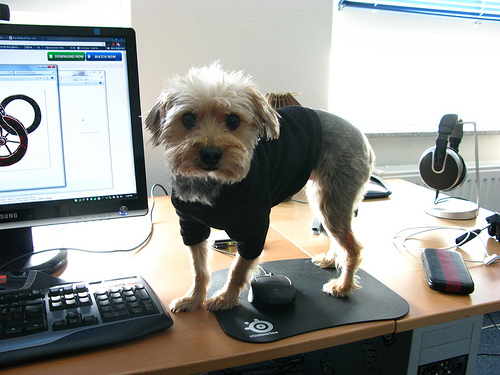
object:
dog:
[145, 64, 376, 314]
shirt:
[172, 105, 321, 259]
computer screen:
[0, 35, 137, 204]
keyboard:
[0, 272, 174, 364]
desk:
[0, 177, 499, 374]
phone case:
[422, 247, 475, 295]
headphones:
[418, 113, 469, 199]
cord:
[394, 224, 499, 266]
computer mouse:
[247, 272, 296, 313]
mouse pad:
[205, 257, 409, 343]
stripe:
[436, 248, 463, 292]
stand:
[428, 121, 480, 221]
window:
[326, 1, 499, 167]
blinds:
[339, 2, 499, 22]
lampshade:
[265, 92, 301, 108]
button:
[47, 51, 85, 61]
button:
[86, 52, 124, 62]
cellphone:
[420, 247, 474, 295]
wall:
[132, 2, 334, 198]